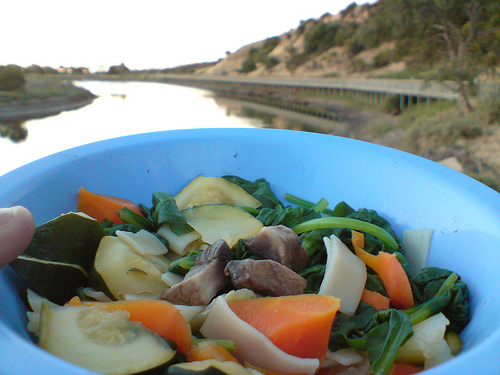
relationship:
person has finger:
[4, 205, 44, 292] [1, 200, 39, 273]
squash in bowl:
[182, 200, 265, 250] [3, 116, 497, 374]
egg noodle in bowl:
[312, 232, 373, 316] [3, 116, 497, 374]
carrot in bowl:
[218, 288, 344, 369] [3, 116, 497, 374]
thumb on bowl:
[1, 200, 39, 273] [3, 116, 497, 374]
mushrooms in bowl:
[165, 215, 310, 307] [3, 116, 497, 374]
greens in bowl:
[260, 183, 376, 238] [3, 116, 497, 374]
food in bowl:
[22, 166, 476, 375] [3, 116, 497, 374]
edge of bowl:
[86, 120, 376, 149] [3, 116, 497, 374]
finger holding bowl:
[1, 200, 39, 273] [3, 116, 497, 374]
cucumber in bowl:
[182, 200, 265, 250] [3, 116, 497, 374]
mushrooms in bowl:
[160, 238, 234, 307] [3, 116, 497, 374]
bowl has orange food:
[3, 116, 497, 374] [218, 288, 344, 369]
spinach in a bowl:
[273, 196, 373, 233] [3, 116, 497, 374]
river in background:
[0, 74, 337, 177] [4, 50, 338, 96]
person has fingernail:
[1, 200, 39, 273] [2, 203, 17, 232]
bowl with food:
[3, 116, 497, 374] [22, 166, 476, 375]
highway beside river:
[160, 68, 445, 112] [1, 74, 248, 140]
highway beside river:
[160, 68, 445, 112] [0, 74, 337, 177]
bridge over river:
[160, 68, 445, 112] [0, 74, 337, 177]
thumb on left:
[1, 200, 39, 273] [1, 4, 30, 366]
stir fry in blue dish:
[22, 166, 476, 375] [3, 116, 497, 374]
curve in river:
[1, 74, 248, 140] [0, 74, 337, 177]